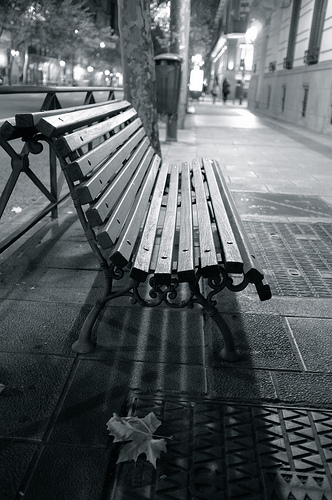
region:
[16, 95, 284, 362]
Bench on the side of the street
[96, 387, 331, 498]
sewer hole next to the bench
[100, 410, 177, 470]
Fallen maple leaf on the ground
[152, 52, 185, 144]
Dust bin on the side of the street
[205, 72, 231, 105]
Two people walking on the street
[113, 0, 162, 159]
Tree trunk next to the bench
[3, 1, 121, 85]
Trees on the side of the street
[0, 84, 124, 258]
Steel fence behind the bench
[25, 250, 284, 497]
Shadow of the bench on the ground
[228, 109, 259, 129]
Reflection of light on the ground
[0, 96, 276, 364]
wooden bench with metal supports on sidewalk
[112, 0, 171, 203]
tree trunk growing through sidewalk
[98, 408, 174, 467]
light colored leaf on sidewalk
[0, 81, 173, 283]
metal fence along sidewalk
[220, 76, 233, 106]
person walking on sidewalk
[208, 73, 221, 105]
person walking on sidewalk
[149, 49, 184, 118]
metal garbage can next to sidewalk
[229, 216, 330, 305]
metal grate in sidewalk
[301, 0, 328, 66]
window covered with metal bars on building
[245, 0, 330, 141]
white and gray building next to sidewalk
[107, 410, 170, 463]
fallen leaf on ground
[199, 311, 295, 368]
leg on the bench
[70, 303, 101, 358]
rear leg on the bench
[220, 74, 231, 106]
woman walking in the distance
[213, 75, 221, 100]
woman in white walking in distance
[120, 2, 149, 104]
tree bark next to bench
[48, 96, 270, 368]
bench on the street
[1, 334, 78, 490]
cement pavement on the ground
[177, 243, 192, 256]
screw in wood bench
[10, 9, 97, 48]
trees across from bench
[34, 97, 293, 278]
bench on the sidewalk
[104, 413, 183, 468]
leaf on the ground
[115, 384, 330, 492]
mat on the ground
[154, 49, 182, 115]
bin for disposing items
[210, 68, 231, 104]
people walking on sidewalk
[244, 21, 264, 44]
lights on the building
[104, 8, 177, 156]
tree by the bench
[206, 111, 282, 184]
sidewalk for pedestrians to walk on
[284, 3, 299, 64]
window on side of building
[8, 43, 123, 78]
lights on the street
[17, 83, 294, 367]
an iron and wooden bench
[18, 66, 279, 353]
a bench on a city sidewalk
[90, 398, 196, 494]
a single leaf on a sidewalk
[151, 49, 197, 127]
a garbage bin on a tree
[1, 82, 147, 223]
an iron fence that separates the sidewalk from the street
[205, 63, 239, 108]
two people walking at night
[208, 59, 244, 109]
two people walking under bright city lights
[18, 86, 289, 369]
the bench is empty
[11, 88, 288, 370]
there is nobody on the bench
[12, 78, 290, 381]
no one is sitting on this bench